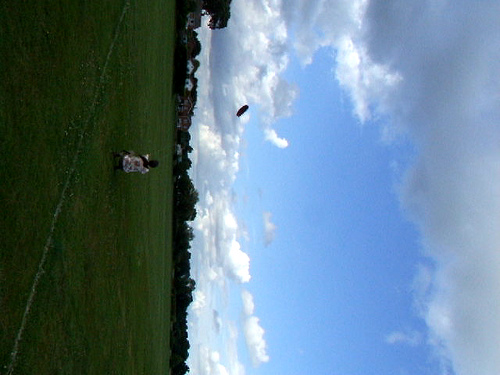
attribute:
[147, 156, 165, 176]
hair — black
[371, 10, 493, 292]
clouds — surrounding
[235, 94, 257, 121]
object — black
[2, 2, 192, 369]
field — large , flat , green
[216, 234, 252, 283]
cloud — white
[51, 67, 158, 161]
line — white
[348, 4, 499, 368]
clouds — dark grey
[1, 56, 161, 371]
grass — green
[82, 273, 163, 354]
grass — green